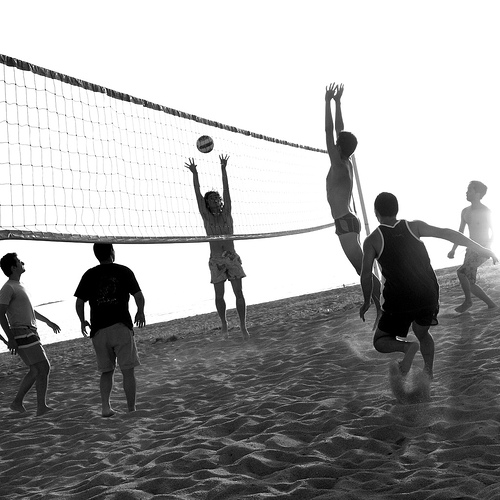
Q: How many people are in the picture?
A: Six.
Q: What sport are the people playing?
A: Volleyball.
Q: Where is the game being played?
A: On a beach.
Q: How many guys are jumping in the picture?
A: Two.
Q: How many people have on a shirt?
A: Three.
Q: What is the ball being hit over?
A: A net.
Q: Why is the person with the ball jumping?
A: To hit the ball.